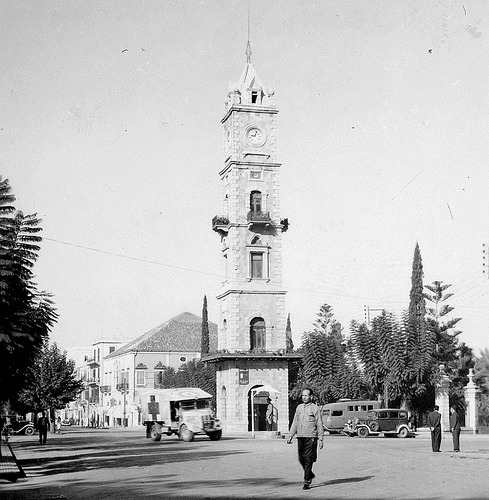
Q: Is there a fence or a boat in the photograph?
A: No, there are no fences or boats.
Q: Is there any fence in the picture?
A: No, there are no fences.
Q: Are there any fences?
A: No, there are no fences.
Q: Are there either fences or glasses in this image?
A: No, there are no glasses or fences.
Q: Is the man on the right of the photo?
A: Yes, the man is on the right of the image.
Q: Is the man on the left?
A: No, the man is on the right of the image.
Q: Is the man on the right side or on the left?
A: The man is on the right of the image.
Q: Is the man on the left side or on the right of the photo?
A: The man is on the right of the image.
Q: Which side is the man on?
A: The man is on the right of the image.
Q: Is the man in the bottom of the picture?
A: Yes, the man is in the bottom of the image.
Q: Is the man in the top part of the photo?
A: No, the man is in the bottom of the image.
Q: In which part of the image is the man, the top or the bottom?
A: The man is in the bottom of the image.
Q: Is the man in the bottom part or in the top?
A: The man is in the bottom of the image.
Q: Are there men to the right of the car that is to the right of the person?
A: Yes, there is a man to the right of the car.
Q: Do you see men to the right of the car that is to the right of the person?
A: Yes, there is a man to the right of the car.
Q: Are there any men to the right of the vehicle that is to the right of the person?
A: Yes, there is a man to the right of the car.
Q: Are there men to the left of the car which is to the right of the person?
A: No, the man is to the right of the car.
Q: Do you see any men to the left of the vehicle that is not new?
A: No, the man is to the right of the car.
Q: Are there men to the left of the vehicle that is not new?
A: No, the man is to the right of the car.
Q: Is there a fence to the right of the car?
A: No, there is a man to the right of the car.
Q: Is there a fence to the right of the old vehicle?
A: No, there is a man to the right of the car.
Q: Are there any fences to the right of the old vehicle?
A: No, there is a man to the right of the car.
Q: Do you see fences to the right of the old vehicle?
A: No, there is a man to the right of the car.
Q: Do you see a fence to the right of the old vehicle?
A: No, there is a man to the right of the car.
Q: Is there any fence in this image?
A: No, there are no fences.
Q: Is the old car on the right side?
A: Yes, the car is on the right of the image.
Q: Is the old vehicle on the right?
A: Yes, the car is on the right of the image.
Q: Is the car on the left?
A: No, the car is on the right of the image.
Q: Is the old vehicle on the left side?
A: No, the car is on the right of the image.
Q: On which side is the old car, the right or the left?
A: The car is on the right of the image.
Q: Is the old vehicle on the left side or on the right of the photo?
A: The car is on the right of the image.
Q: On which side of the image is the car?
A: The car is on the right of the image.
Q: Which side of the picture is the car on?
A: The car is on the right of the image.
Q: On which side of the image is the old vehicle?
A: The car is on the right of the image.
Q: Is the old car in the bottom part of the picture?
A: Yes, the car is in the bottom of the image.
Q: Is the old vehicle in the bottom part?
A: Yes, the car is in the bottom of the image.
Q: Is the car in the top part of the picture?
A: No, the car is in the bottom of the image.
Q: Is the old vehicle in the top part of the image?
A: No, the car is in the bottom of the image.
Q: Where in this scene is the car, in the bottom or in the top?
A: The car is in the bottom of the image.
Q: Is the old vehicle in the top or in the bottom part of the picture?
A: The car is in the bottom of the image.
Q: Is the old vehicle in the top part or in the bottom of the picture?
A: The car is in the bottom of the image.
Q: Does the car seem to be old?
A: Yes, the car is old.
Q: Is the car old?
A: Yes, the car is old.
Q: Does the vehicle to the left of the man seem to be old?
A: Yes, the car is old.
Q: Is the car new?
A: No, the car is old.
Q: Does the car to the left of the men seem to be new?
A: No, the car is old.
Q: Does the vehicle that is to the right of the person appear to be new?
A: No, the car is old.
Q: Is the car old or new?
A: The car is old.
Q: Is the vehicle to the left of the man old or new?
A: The car is old.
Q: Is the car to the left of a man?
A: Yes, the car is to the left of a man.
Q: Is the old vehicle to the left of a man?
A: Yes, the car is to the left of a man.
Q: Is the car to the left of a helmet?
A: No, the car is to the left of a man.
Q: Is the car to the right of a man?
A: No, the car is to the left of a man.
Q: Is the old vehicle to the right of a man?
A: No, the car is to the left of a man.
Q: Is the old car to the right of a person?
A: Yes, the car is to the right of a person.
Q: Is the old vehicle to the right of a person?
A: Yes, the car is to the right of a person.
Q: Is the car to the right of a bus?
A: No, the car is to the right of a person.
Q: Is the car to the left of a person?
A: No, the car is to the right of a person.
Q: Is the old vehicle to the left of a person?
A: No, the car is to the right of a person.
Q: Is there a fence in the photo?
A: No, there are no fences.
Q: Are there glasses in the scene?
A: No, there are no glasses.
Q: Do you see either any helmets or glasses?
A: No, there are no glasses or helmets.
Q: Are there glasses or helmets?
A: No, there are no glasses or helmets.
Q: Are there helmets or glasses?
A: No, there are no glasses or helmets.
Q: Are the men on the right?
A: Yes, the men are on the right of the image.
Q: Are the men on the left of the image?
A: No, the men are on the right of the image.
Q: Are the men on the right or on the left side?
A: The men are on the right of the image.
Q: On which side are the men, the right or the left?
A: The men are on the right of the image.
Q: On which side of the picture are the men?
A: The men are on the right of the image.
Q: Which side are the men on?
A: The men are on the right of the image.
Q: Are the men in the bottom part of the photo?
A: Yes, the men are in the bottom of the image.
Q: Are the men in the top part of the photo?
A: No, the men are in the bottom of the image.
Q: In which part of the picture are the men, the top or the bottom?
A: The men are in the bottom of the image.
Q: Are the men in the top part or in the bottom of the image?
A: The men are in the bottom of the image.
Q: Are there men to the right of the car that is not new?
A: Yes, there are men to the right of the car.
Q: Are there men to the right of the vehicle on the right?
A: Yes, there are men to the right of the car.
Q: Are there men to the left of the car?
A: No, the men are to the right of the car.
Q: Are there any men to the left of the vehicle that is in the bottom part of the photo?
A: No, the men are to the right of the car.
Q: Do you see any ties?
A: No, there are no ties.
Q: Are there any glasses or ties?
A: No, there are no ties or glasses.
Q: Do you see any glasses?
A: No, there are no glasses.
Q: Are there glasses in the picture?
A: No, there are no glasses.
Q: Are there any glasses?
A: No, there are no glasses.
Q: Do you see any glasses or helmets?
A: No, there are no glasses or helmets.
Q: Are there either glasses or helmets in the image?
A: No, there are no glasses or helmets.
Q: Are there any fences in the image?
A: No, there are no fences.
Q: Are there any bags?
A: No, there are no bags.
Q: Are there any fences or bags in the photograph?
A: No, there are no bags or fences.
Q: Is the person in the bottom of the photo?
A: Yes, the person is in the bottom of the image.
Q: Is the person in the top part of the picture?
A: No, the person is in the bottom of the image.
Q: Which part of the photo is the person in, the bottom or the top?
A: The person is in the bottom of the image.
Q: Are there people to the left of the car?
A: Yes, there is a person to the left of the car.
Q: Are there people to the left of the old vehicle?
A: Yes, there is a person to the left of the car.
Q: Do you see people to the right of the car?
A: No, the person is to the left of the car.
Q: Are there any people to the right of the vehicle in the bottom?
A: No, the person is to the left of the car.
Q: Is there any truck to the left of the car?
A: No, there is a person to the left of the car.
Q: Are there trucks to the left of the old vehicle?
A: No, there is a person to the left of the car.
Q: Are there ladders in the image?
A: No, there are no ladders.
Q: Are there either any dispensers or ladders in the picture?
A: No, there are no ladders or dispensers.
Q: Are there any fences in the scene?
A: No, there are no fences.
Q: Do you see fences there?
A: No, there are no fences.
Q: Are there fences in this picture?
A: No, there are no fences.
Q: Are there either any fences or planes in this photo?
A: No, there are no fences or planes.